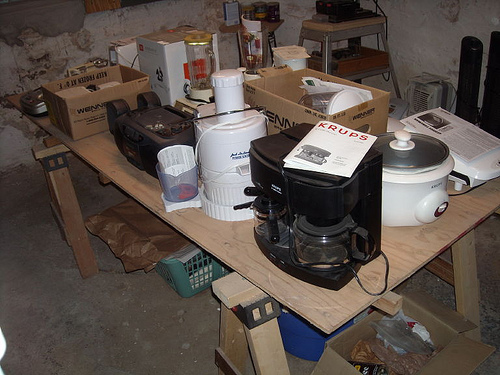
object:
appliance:
[371, 130, 454, 227]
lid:
[370, 129, 449, 168]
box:
[243, 67, 390, 136]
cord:
[303, 250, 390, 296]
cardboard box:
[312, 288, 496, 374]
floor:
[2, 292, 197, 371]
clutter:
[84, 198, 189, 273]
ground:
[60, 300, 108, 346]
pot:
[369, 130, 455, 227]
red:
[349, 133, 358, 138]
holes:
[188, 265, 192, 272]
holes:
[192, 256, 196, 263]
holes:
[199, 262, 203, 268]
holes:
[194, 271, 199, 277]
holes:
[203, 259, 207, 266]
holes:
[199, 275, 204, 281]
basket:
[154, 244, 230, 297]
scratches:
[252, 266, 349, 334]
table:
[6, 91, 500, 375]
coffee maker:
[232, 123, 389, 296]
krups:
[318, 123, 368, 141]